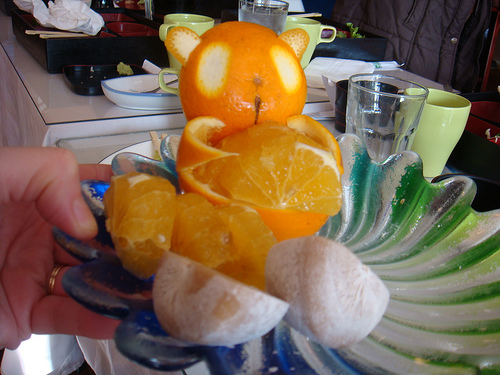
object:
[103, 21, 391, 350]
fruit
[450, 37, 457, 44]
jacket button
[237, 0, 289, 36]
glass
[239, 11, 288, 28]
water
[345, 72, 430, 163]
cup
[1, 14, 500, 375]
table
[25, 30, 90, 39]
chopsticks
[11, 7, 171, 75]
tray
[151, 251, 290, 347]
slice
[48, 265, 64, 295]
band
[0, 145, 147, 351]
hand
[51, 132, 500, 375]
bowl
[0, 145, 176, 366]
person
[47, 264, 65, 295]
rings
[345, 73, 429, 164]
glass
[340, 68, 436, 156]
knife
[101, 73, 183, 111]
dish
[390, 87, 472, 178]
cup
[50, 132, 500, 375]
plate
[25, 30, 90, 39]
utensil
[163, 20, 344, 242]
bear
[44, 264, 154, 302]
finger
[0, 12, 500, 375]
counter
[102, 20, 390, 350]
oranges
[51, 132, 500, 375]
dish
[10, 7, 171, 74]
box